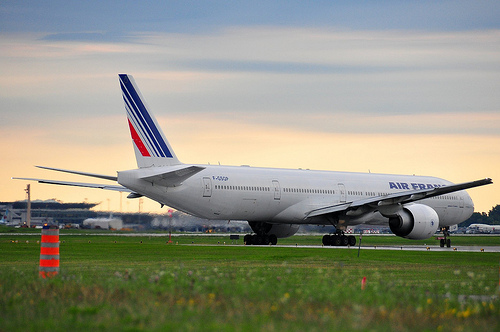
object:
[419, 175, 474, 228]
front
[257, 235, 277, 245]
wheel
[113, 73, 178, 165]
wing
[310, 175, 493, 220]
wing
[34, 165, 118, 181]
wing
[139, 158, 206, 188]
wing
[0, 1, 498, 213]
blue sky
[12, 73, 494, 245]
plane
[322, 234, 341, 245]
wheel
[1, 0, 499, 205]
clouds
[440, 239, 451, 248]
wheel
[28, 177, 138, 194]
wing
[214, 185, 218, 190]
window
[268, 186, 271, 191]
window